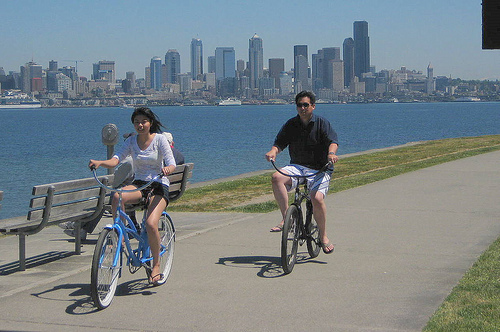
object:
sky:
[0, 0, 499, 83]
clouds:
[0, 0, 499, 80]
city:
[0, 18, 499, 106]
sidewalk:
[0, 148, 499, 330]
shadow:
[212, 250, 328, 279]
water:
[0, 103, 499, 220]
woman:
[88, 106, 177, 284]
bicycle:
[86, 159, 178, 309]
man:
[261, 90, 341, 255]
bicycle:
[265, 155, 333, 273]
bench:
[0, 162, 195, 272]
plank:
[29, 161, 195, 196]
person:
[161, 131, 186, 168]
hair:
[161, 130, 175, 145]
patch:
[164, 134, 500, 215]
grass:
[158, 134, 500, 214]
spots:
[238, 193, 275, 205]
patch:
[423, 234, 500, 332]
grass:
[418, 234, 500, 331]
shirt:
[112, 132, 175, 187]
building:
[351, 19, 369, 83]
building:
[223, 50, 237, 79]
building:
[329, 59, 344, 93]